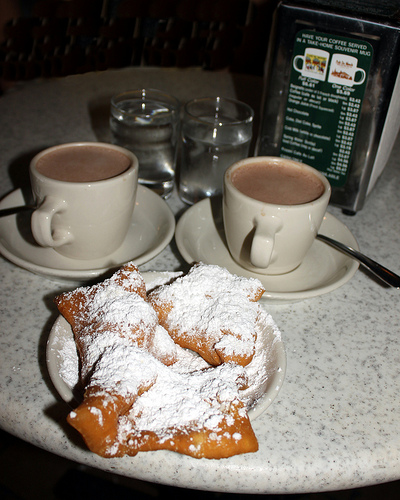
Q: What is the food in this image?
A: The food is a pastry.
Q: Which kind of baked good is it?
A: The food is a pastry.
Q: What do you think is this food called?
A: That is a pastry.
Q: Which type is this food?
A: That is a pastry.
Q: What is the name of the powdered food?
A: The food is a pastry.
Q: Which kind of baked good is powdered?
A: The baked good is a pastry.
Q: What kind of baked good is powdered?
A: The baked good is a pastry.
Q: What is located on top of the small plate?
A: The pastry is on top of the plate.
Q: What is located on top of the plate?
A: The pastry is on top of the plate.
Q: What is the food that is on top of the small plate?
A: The food is a pastry.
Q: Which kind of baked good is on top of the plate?
A: The food is a pastry.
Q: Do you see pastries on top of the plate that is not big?
A: Yes, there is a pastry on top of the plate.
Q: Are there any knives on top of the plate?
A: No, there is a pastry on top of the plate.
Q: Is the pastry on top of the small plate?
A: Yes, the pastry is on top of the plate.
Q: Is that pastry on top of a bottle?
A: No, the pastry is on top of the plate.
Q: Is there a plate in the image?
A: Yes, there is a plate.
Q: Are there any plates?
A: Yes, there is a plate.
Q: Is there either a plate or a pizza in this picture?
A: Yes, there is a plate.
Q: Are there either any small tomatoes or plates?
A: Yes, there is a small plate.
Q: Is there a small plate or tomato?
A: Yes, there is a small plate.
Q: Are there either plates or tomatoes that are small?
A: Yes, the plate is small.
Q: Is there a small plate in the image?
A: Yes, there is a small plate.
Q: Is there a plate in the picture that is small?
A: Yes, there is a plate that is small.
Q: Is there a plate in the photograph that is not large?
A: Yes, there is a small plate.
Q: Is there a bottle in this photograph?
A: No, there are no bottles.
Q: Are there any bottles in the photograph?
A: No, there are no bottles.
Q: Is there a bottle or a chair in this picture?
A: No, there are no bottles or chairs.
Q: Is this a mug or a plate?
A: This is a plate.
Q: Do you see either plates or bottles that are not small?
A: No, there is a plate but it is small.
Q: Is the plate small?
A: Yes, the plate is small.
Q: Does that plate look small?
A: Yes, the plate is small.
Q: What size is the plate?
A: The plate is small.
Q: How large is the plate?
A: The plate is small.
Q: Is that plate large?
A: No, the plate is small.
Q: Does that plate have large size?
A: No, the plate is small.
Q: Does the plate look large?
A: No, the plate is small.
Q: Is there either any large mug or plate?
A: No, there is a plate but it is small.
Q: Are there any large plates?
A: No, there is a plate but it is small.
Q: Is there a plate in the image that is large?
A: No, there is a plate but it is small.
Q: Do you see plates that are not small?
A: No, there is a plate but it is small.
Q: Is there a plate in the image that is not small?
A: No, there is a plate but it is small.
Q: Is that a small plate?
A: Yes, that is a small plate.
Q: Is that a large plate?
A: No, that is a small plate.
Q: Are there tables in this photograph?
A: Yes, there is a table.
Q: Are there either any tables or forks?
A: Yes, there is a table.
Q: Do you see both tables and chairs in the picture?
A: No, there is a table but no chairs.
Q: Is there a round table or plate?
A: Yes, there is a round table.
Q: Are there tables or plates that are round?
A: Yes, the table is round.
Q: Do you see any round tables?
A: Yes, there is a round table.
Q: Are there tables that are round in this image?
A: Yes, there is a round table.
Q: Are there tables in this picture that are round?
A: Yes, there is a table that is round.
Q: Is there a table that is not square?
A: Yes, there is a round table.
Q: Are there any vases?
A: No, there are no vases.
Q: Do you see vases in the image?
A: No, there are no vases.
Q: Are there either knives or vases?
A: No, there are no vases or knives.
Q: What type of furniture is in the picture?
A: The furniture is a table.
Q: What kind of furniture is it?
A: The piece of furniture is a table.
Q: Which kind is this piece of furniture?
A: This is a table.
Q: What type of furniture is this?
A: This is a table.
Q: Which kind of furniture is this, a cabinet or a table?
A: This is a table.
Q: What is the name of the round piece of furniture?
A: The piece of furniture is a table.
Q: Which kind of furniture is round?
A: The furniture is a table.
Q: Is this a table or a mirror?
A: This is a table.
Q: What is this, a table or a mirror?
A: This is a table.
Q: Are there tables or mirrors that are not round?
A: No, there is a table but it is round.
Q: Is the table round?
A: Yes, the table is round.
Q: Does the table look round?
A: Yes, the table is round.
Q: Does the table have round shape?
A: Yes, the table is round.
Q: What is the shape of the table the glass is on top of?
A: The table is round.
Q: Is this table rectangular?
A: No, the table is round.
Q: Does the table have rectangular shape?
A: No, the table is round.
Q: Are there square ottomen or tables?
A: No, there is a table but it is round.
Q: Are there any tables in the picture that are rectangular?
A: No, there is a table but it is round.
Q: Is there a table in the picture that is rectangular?
A: No, there is a table but it is round.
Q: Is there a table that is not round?
A: No, there is a table but it is round.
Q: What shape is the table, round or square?
A: The table is round.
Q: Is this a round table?
A: Yes, this is a round table.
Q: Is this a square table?
A: No, this is a round table.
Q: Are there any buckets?
A: No, there are no buckets.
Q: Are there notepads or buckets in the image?
A: No, there are no buckets or notepads.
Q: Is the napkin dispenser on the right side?
A: Yes, the napkin dispenser is on the right of the image.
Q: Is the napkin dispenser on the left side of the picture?
A: No, the napkin dispenser is on the right of the image.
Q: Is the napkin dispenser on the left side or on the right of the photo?
A: The napkin dispenser is on the right of the image.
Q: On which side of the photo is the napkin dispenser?
A: The napkin dispenser is on the right of the image.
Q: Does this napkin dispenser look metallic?
A: Yes, the napkin dispenser is metallic.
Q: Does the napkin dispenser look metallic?
A: Yes, the napkin dispenser is metallic.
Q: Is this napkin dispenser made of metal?
A: Yes, the napkin dispenser is made of metal.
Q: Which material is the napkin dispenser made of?
A: The napkin dispenser is made of metal.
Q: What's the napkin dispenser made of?
A: The napkin dispenser is made of metal.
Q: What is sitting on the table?
A: The napkin dispenser is sitting on the table.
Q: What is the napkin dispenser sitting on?
A: The napkin dispenser is sitting on the table.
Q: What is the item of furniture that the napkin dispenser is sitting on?
A: The piece of furniture is a table.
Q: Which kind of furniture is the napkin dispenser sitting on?
A: The napkin dispenser is sitting on the table.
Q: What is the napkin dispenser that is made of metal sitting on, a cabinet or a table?
A: The napkin dispenser is sitting on a table.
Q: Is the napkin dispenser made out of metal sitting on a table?
A: Yes, the napkin dispenser is sitting on a table.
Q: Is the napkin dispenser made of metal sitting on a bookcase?
A: No, the napkin dispenser is sitting on a table.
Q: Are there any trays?
A: No, there are no trays.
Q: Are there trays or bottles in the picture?
A: No, there are no trays or bottles.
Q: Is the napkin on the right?
A: Yes, the napkin is on the right of the image.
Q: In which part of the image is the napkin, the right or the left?
A: The napkin is on the right of the image.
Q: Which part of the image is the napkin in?
A: The napkin is on the right of the image.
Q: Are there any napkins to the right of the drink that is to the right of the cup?
A: Yes, there is a napkin to the right of the coffee.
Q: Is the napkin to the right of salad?
A: No, the napkin is to the right of the coffee.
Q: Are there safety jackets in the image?
A: No, there are no safety jackets.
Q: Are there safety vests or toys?
A: No, there are no safety vests or toys.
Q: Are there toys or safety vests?
A: No, there are no safety vests or toys.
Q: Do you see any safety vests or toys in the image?
A: No, there are no safety vests or toys.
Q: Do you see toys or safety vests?
A: No, there are no safety vests or toys.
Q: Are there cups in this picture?
A: Yes, there is a cup.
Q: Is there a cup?
A: Yes, there is a cup.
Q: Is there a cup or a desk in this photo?
A: Yes, there is a cup.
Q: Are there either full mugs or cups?
A: Yes, there is a full cup.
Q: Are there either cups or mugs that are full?
A: Yes, the cup is full.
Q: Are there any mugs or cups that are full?
A: Yes, the cup is full.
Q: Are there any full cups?
A: Yes, there is a full cup.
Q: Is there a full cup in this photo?
A: Yes, there is a full cup.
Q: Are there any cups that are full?
A: Yes, there is a cup that is full.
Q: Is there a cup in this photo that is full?
A: Yes, there is a cup that is full.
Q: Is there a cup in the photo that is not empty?
A: Yes, there is an full cup.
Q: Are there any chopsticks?
A: No, there are no chopsticks.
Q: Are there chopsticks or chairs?
A: No, there are no chopsticks or chairs.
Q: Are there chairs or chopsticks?
A: No, there are no chopsticks or chairs.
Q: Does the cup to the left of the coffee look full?
A: Yes, the cup is full.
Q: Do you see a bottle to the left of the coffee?
A: No, there is a cup to the left of the coffee.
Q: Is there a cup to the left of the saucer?
A: Yes, there is a cup to the left of the saucer.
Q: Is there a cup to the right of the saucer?
A: No, the cup is to the left of the saucer.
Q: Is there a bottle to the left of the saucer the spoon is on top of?
A: No, there is a cup to the left of the saucer.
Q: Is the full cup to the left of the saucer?
A: Yes, the cup is to the left of the saucer.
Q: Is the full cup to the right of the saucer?
A: No, the cup is to the left of the saucer.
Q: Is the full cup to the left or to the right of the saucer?
A: The cup is to the left of the saucer.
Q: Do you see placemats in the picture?
A: No, there are no placemats.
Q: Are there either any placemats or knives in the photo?
A: No, there are no placemats or knives.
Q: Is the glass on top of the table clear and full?
A: Yes, the glass is clear and full.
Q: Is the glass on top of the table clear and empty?
A: No, the glass is clear but full.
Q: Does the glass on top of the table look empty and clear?
A: No, the glass is clear but full.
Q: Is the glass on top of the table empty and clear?
A: No, the glass is clear but full.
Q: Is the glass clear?
A: Yes, the glass is clear.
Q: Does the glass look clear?
A: Yes, the glass is clear.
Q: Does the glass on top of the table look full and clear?
A: Yes, the glass is full and clear.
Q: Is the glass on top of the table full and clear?
A: Yes, the glass is full and clear.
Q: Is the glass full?
A: Yes, the glass is full.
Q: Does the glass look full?
A: Yes, the glass is full.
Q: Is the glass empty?
A: No, the glass is full.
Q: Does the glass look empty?
A: No, the glass is full.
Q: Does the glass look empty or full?
A: The glass is full.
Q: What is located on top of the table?
A: The glass is on top of the table.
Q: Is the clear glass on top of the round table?
A: Yes, the glass is on top of the table.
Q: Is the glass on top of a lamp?
A: No, the glass is on top of the table.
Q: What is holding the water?
A: The glass is holding the water.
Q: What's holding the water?
A: The glass is holding the water.